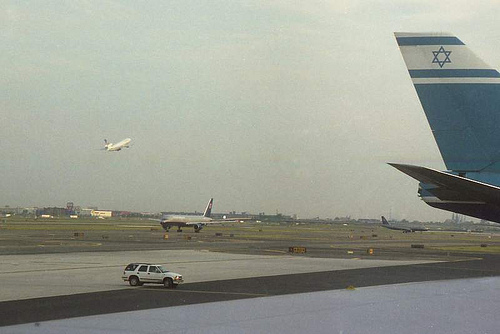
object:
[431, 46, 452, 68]
star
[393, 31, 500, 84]
white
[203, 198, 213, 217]
tail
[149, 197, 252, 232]
plane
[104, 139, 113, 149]
tail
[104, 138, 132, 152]
plane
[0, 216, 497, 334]
ground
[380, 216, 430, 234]
plane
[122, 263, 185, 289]
car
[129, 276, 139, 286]
wheel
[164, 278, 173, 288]
wheel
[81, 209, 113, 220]
building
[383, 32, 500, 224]
plane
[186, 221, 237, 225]
wing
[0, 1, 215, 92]
sky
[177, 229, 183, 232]
wheel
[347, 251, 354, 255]
object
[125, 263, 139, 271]
windows